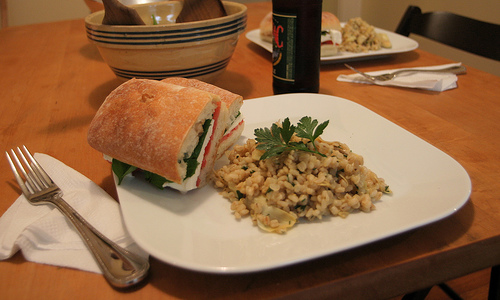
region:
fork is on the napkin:
[0, 144, 142, 291]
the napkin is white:
[8, 159, 143, 277]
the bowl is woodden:
[76, 9, 257, 84]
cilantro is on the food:
[252, 115, 336, 167]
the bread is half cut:
[101, 83, 225, 192]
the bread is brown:
[92, 81, 207, 181]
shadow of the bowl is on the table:
[226, 67, 260, 93]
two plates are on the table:
[123, 13, 471, 282]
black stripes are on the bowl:
[149, 24, 215, 46]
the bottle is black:
[270, 3, 327, 93]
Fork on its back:
[3, 142, 153, 295]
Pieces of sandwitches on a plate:
[86, 73, 250, 195]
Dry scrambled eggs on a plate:
[207, 117, 402, 240]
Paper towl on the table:
[0, 151, 155, 280]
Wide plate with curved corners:
[95, 87, 494, 284]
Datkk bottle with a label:
[265, 1, 328, 98]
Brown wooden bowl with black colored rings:
[80, 1, 247, 83]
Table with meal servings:
[0, 0, 498, 299]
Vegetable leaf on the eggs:
[247, 113, 332, 168]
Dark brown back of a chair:
[392, 3, 498, 72]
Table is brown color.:
[11, 35, 103, 145]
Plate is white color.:
[98, 86, 476, 258]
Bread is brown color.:
[93, 77, 193, 179]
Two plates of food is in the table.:
[220, 9, 440, 210]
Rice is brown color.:
[212, 114, 382, 236]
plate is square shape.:
[57, 84, 495, 270]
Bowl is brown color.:
[63, 5, 255, 90]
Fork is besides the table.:
[6, 139, 118, 299]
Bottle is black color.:
[263, 4, 325, 97]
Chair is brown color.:
[384, 8, 499, 69]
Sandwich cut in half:
[77, 66, 240, 202]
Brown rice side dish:
[225, 130, 380, 228]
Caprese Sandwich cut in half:
[91, 80, 237, 190]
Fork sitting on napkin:
[0, 143, 135, 279]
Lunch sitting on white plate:
[105, 100, 475, 277]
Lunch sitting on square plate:
[100, 90, 475, 275]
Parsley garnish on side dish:
[226, 111, 367, 226]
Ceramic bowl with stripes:
[80, 10, 255, 85]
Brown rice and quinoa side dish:
[216, 121, 391, 231]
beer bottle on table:
[270, 0, 323, 97]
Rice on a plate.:
[204, 120, 398, 242]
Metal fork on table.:
[2, 134, 138, 299]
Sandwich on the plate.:
[92, 63, 261, 198]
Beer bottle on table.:
[270, 4, 327, 90]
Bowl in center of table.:
[79, 3, 263, 73]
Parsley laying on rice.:
[256, 108, 353, 170]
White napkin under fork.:
[6, 196, 153, 274]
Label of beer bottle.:
[266, 8, 298, 86]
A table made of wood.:
[23, 36, 97, 158]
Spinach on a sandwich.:
[110, 157, 183, 196]